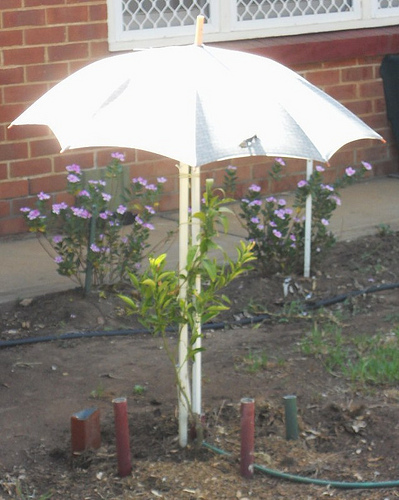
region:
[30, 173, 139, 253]
Purple flower tops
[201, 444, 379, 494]
Garden hose in a yard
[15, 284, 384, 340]
Black garden hose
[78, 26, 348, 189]
Umbrella in a garden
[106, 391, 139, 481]
Red pole in a garden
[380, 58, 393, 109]
Black garbage pail in a yard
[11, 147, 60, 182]
Red brick wall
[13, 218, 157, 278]
Gray sidewalk behind flowers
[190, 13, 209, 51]
Tip of white umbrella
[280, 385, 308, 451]
Green pole in yard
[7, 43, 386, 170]
umbrella canopy is white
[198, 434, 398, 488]
green rubber hose on the ground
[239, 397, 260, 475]
short red post in the ground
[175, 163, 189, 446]
white pole supports umbrella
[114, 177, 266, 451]
green plant under umbrella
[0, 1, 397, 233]
brick wall behind umbrella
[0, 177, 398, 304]
cement sidewalk next to wall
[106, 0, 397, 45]
white window on wall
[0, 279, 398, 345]
black rubber hose on ground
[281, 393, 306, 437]
small green pipe in ground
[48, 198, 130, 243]
purple flowers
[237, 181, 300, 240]
purple flowers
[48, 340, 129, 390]
dirt on the ground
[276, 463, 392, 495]
a green water hose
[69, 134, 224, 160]
a white umbrella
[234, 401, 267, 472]
a red pipe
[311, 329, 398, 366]
green grass in the dirt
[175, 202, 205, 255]
a white pole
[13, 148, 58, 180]
a brick wall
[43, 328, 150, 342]
a black hose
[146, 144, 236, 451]
a plant growing with two stakes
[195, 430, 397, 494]
a hose for watering the plant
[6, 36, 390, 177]
a shade for the plant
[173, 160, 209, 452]
two white stakes for the plant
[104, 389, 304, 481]
low stakes around the plant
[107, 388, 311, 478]
two red and one green stake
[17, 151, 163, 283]
purple flowers in the background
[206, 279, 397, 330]
watering hose in the background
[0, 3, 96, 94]
brick wall of the building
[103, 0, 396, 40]
lattice work on the windows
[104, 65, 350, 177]
white umbrealla overhead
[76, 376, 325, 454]
multiple poles coming from the ground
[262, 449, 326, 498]
green hose attatched to poles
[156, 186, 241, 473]
two white poles under umbrella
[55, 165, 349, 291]
two plants of purple flowers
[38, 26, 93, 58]
red brick wall on building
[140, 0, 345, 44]
white lattice designed window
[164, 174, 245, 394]
green plant growing in ground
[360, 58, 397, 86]
black trash can outside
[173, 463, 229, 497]
a light colored portion of dirt